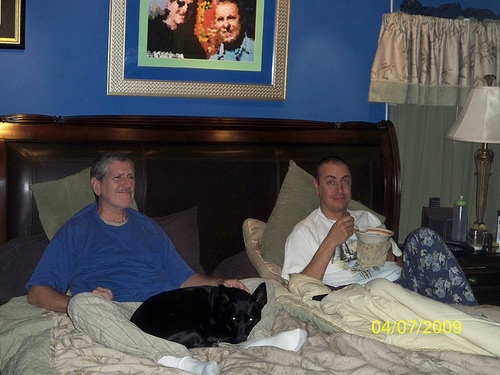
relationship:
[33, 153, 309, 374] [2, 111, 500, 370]
man sitting on bed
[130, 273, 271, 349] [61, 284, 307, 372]
dog laying between legs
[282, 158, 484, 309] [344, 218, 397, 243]
man holding bowl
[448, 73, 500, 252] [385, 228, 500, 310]
lamp on night table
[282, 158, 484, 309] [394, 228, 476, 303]
man wearing pajama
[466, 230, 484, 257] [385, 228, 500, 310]
glass on night table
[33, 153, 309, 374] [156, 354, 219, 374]
man has sock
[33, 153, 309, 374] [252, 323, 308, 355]
man has sock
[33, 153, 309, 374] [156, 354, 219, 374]
man wearing sock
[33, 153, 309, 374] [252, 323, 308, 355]
man wearing sock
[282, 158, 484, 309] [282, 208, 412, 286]
man wearing shirt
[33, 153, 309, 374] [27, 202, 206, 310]
man wearing shirt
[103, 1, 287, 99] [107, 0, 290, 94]
picture has frame